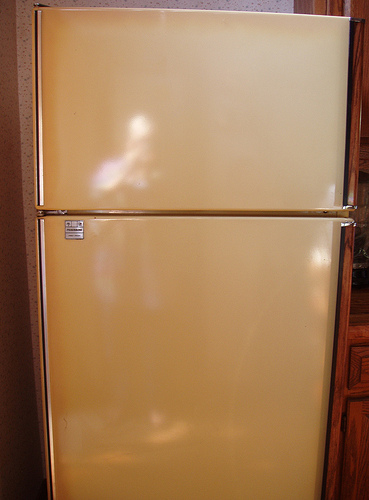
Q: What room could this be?
A: It is a kitchen.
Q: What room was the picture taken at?
A: It was taken at the kitchen.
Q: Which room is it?
A: It is a kitchen.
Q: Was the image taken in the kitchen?
A: Yes, it was taken in the kitchen.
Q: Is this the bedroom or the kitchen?
A: It is the kitchen.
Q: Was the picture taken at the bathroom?
A: No, the picture was taken in the kitchen.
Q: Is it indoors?
A: Yes, it is indoors.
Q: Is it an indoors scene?
A: Yes, it is indoors.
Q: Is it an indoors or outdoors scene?
A: It is indoors.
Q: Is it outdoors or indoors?
A: It is indoors.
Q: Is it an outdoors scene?
A: No, it is indoors.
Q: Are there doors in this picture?
A: Yes, there is a door.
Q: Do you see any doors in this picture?
A: Yes, there is a door.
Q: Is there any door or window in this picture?
A: Yes, there is a door.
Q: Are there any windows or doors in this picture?
A: Yes, there is a door.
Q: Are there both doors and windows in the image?
A: No, there is a door but no windows.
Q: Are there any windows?
A: No, there are no windows.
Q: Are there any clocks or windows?
A: No, there are no windows or clocks.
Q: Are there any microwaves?
A: No, there are no microwaves.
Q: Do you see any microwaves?
A: No, there are no microwaves.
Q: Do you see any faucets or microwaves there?
A: No, there are no microwaves or faucets.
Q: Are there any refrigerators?
A: Yes, there is a refrigerator.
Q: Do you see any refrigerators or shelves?
A: Yes, there is a refrigerator.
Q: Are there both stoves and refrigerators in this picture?
A: No, there is a refrigerator but no stoves.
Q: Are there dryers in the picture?
A: No, there are no dryers.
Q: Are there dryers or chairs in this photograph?
A: No, there are no dryers or chairs.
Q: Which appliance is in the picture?
A: The appliance is a refrigerator.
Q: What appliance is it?
A: The appliance is a refrigerator.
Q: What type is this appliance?
A: This is a refrigerator.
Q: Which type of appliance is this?
A: This is a refrigerator.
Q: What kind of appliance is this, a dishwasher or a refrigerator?
A: This is a refrigerator.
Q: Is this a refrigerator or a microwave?
A: This is a refrigerator.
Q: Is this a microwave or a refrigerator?
A: This is a refrigerator.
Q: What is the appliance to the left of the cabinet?
A: The appliance is a refrigerator.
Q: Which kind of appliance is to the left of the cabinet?
A: The appliance is a refrigerator.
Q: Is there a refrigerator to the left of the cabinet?
A: Yes, there is a refrigerator to the left of the cabinet.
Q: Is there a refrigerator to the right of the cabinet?
A: No, the refrigerator is to the left of the cabinet.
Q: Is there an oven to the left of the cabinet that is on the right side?
A: No, there is a refrigerator to the left of the cabinet.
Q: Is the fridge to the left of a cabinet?
A: Yes, the fridge is to the left of a cabinet.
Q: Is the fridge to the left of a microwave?
A: No, the fridge is to the left of a cabinet.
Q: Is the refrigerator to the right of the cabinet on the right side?
A: No, the refrigerator is to the left of the cabinet.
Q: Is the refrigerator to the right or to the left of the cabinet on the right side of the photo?
A: The refrigerator is to the left of the cabinet.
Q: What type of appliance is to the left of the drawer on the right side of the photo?
A: The appliance is a refrigerator.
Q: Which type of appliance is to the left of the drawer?
A: The appliance is a refrigerator.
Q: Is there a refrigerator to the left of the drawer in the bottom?
A: Yes, there is a refrigerator to the left of the drawer.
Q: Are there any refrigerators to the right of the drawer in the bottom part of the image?
A: No, the refrigerator is to the left of the drawer.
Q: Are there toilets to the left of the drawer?
A: No, there is a refrigerator to the left of the drawer.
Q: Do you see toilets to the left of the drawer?
A: No, there is a refrigerator to the left of the drawer.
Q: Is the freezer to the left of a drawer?
A: Yes, the freezer is to the left of a drawer.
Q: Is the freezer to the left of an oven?
A: No, the freezer is to the left of a drawer.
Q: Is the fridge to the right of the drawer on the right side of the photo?
A: No, the fridge is to the left of the drawer.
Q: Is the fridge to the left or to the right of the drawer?
A: The fridge is to the left of the drawer.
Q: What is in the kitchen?
A: The fridge is in the kitchen.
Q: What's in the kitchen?
A: The fridge is in the kitchen.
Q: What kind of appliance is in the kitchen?
A: The appliance is a refrigerator.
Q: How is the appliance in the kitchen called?
A: The appliance is a refrigerator.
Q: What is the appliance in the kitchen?
A: The appliance is a refrigerator.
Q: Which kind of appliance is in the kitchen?
A: The appliance is a refrigerator.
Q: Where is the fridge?
A: The fridge is in the kitchen.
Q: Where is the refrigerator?
A: The fridge is in the kitchen.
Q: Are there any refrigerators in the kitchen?
A: Yes, there is a refrigerator in the kitchen.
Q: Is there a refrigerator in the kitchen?
A: Yes, there is a refrigerator in the kitchen.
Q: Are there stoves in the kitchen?
A: No, there is a refrigerator in the kitchen.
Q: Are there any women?
A: No, there are no women.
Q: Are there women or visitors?
A: No, there are no women or visitors.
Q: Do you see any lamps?
A: No, there are no lamps.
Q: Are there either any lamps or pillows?
A: No, there are no lamps or pillows.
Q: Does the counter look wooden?
A: Yes, the counter is wooden.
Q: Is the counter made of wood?
A: Yes, the counter is made of wood.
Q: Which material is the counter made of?
A: The counter is made of wood.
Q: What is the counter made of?
A: The counter is made of wood.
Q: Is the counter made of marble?
A: No, the counter is made of wood.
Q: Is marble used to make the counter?
A: No, the counter is made of wood.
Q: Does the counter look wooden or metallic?
A: The counter is wooden.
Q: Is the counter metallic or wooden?
A: The counter is wooden.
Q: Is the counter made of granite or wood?
A: The counter is made of wood.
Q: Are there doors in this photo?
A: Yes, there are doors.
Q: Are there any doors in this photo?
A: Yes, there are doors.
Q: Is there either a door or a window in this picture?
A: Yes, there are doors.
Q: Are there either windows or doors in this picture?
A: Yes, there are doors.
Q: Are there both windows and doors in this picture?
A: No, there are doors but no windows.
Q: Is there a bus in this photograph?
A: No, there are no buses.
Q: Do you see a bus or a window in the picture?
A: No, there are no buses or windows.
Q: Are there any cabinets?
A: Yes, there is a cabinet.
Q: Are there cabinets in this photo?
A: Yes, there is a cabinet.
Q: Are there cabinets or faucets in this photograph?
A: Yes, there is a cabinet.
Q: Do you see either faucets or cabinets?
A: Yes, there is a cabinet.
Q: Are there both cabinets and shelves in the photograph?
A: No, there is a cabinet but no shelves.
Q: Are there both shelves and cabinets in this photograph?
A: No, there is a cabinet but no shelves.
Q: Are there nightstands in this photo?
A: No, there are no nightstands.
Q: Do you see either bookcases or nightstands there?
A: No, there are no nightstands or bookcases.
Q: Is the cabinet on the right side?
A: Yes, the cabinet is on the right of the image.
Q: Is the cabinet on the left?
A: No, the cabinet is on the right of the image.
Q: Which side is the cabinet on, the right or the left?
A: The cabinet is on the right of the image.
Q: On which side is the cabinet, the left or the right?
A: The cabinet is on the right of the image.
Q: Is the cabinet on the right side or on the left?
A: The cabinet is on the right of the image.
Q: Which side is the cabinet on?
A: The cabinet is on the right of the image.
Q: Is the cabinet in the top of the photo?
A: Yes, the cabinet is in the top of the image.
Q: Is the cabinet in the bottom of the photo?
A: No, the cabinet is in the top of the image.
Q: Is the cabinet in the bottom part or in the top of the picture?
A: The cabinet is in the top of the image.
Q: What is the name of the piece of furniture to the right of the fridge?
A: The piece of furniture is a cabinet.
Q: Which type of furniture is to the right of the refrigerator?
A: The piece of furniture is a cabinet.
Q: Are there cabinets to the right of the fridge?
A: Yes, there is a cabinet to the right of the fridge.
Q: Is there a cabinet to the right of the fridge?
A: Yes, there is a cabinet to the right of the fridge.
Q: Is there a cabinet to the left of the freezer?
A: No, the cabinet is to the right of the freezer.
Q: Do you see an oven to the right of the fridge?
A: No, there is a cabinet to the right of the fridge.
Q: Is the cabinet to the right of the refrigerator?
A: Yes, the cabinet is to the right of the refrigerator.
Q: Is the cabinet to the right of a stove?
A: No, the cabinet is to the right of the refrigerator.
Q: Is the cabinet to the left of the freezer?
A: No, the cabinet is to the right of the freezer.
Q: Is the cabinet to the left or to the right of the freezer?
A: The cabinet is to the right of the freezer.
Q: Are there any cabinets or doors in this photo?
A: Yes, there are doors.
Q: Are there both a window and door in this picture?
A: No, there are doors but no windows.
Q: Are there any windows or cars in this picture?
A: No, there are no windows or cars.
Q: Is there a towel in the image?
A: No, there are no towels.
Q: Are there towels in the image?
A: No, there are no towels.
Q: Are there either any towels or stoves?
A: No, there are no towels or stoves.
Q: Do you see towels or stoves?
A: No, there are no towels or stoves.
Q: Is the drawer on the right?
A: Yes, the drawer is on the right of the image.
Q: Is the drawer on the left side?
A: No, the drawer is on the right of the image.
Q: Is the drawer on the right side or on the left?
A: The drawer is on the right of the image.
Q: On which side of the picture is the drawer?
A: The drawer is on the right of the image.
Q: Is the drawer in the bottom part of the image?
A: Yes, the drawer is in the bottom of the image.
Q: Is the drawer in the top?
A: No, the drawer is in the bottom of the image.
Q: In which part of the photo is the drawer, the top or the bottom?
A: The drawer is in the bottom of the image.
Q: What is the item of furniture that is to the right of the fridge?
A: The piece of furniture is a drawer.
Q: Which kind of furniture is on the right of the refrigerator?
A: The piece of furniture is a drawer.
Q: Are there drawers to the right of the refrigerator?
A: Yes, there is a drawer to the right of the refrigerator.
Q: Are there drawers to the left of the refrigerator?
A: No, the drawer is to the right of the refrigerator.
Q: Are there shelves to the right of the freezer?
A: No, there is a drawer to the right of the freezer.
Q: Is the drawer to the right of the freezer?
A: Yes, the drawer is to the right of the freezer.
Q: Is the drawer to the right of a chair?
A: No, the drawer is to the right of the freezer.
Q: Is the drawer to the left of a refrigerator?
A: No, the drawer is to the right of a refrigerator.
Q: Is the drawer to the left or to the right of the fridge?
A: The drawer is to the right of the fridge.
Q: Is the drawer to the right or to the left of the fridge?
A: The drawer is to the right of the fridge.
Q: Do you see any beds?
A: No, there are no beds.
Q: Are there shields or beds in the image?
A: No, there are no beds or shields.